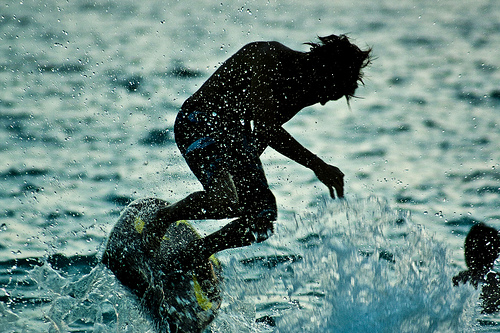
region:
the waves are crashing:
[321, 249, 434, 311]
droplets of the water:
[57, 83, 130, 144]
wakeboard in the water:
[110, 263, 207, 325]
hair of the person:
[306, 30, 366, 100]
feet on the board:
[153, 229, 195, 286]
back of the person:
[209, 68, 257, 91]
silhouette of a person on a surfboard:
[103, 30, 371, 327]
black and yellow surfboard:
[103, 195, 225, 330]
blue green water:
[0, 3, 497, 330]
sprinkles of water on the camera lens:
[0, 3, 499, 331]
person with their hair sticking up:
[98, 29, 373, 327]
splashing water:
[33, 187, 453, 330]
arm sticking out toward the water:
[261, 127, 348, 197]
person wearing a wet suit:
[144, 33, 373, 274]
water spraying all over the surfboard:
[98, 190, 223, 328]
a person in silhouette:
[453, 218, 498, 325]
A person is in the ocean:
[55, 15, 466, 330]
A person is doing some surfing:
[43, 25, 463, 306]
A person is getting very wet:
[78, 30, 419, 326]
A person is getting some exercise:
[55, 22, 461, 307]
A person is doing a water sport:
[53, 1, 498, 326]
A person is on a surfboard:
[35, 10, 461, 320]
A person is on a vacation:
[37, 18, 452, 319]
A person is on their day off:
[46, 16, 446, 321]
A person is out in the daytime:
[57, 7, 414, 325]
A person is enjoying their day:
[90, 13, 389, 323]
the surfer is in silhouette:
[100, 32, 384, 323]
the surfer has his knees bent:
[91, 26, 372, 331]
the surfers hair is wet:
[303, 25, 380, 112]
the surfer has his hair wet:
[101, 30, 371, 328]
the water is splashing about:
[101, 31, 377, 327]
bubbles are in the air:
[30, 10, 168, 169]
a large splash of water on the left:
[268, 190, 486, 329]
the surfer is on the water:
[95, 8, 377, 330]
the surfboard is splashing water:
[13, 245, 157, 332]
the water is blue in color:
[3, 2, 498, 330]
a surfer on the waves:
[15, 11, 471, 330]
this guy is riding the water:
[84, 7, 384, 327]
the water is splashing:
[49, 15, 430, 330]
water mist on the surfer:
[98, 30, 303, 261]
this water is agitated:
[34, 187, 459, 332]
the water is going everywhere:
[227, 192, 498, 318]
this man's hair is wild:
[293, 20, 405, 115]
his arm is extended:
[272, 124, 371, 208]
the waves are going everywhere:
[24, 22, 160, 165]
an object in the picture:
[443, 209, 499, 324]